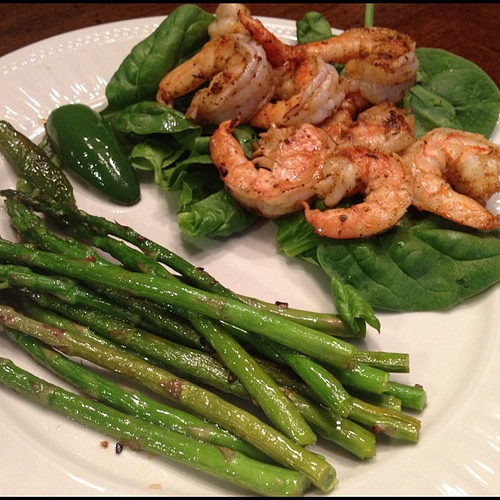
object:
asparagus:
[0, 358, 312, 496]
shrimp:
[153, 23, 275, 131]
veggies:
[174, 169, 264, 241]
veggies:
[410, 45, 500, 142]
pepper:
[43, 104, 144, 208]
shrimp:
[402, 124, 499, 235]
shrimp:
[298, 146, 413, 241]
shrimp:
[204, 0, 294, 68]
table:
[0, 0, 499, 86]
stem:
[50, 215, 317, 450]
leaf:
[98, 3, 217, 117]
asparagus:
[0, 303, 338, 495]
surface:
[0, 14, 499, 499]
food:
[0, 118, 83, 215]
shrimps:
[320, 91, 417, 157]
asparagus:
[0, 237, 359, 374]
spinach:
[96, 101, 202, 149]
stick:
[350, 345, 410, 374]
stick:
[4, 325, 316, 468]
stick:
[15, 284, 378, 463]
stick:
[250, 357, 420, 445]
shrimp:
[292, 25, 421, 108]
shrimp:
[246, 51, 346, 132]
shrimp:
[207, 118, 335, 217]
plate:
[0, 0, 499, 498]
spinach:
[273, 191, 499, 336]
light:
[461, 465, 498, 499]